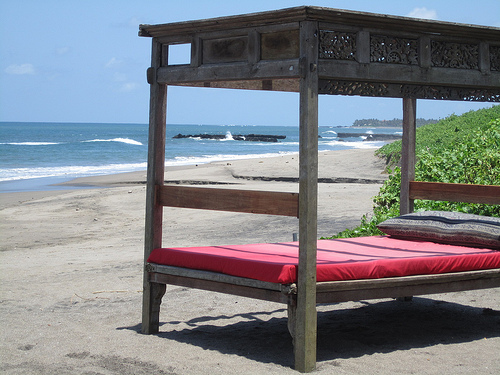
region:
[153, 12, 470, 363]
bed on beach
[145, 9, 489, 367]
bed on sand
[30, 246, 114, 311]
tan sand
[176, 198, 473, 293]
red mattress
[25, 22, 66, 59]
white clouds in blue sky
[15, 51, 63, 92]
white clouds in blue sky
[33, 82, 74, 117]
white clouds in blue sky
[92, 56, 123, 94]
white clouds in blue sky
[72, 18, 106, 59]
white clouds in blue sky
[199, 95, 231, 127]
white clouds in blue sky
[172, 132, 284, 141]
wall of rocks in ocean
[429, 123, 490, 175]
green grass on hill side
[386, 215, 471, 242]
grey and white pillows on red bed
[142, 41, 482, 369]
wooden bed on beach by ocean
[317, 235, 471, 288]
red bed mattress on wooden frame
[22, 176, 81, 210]
sandy beach by ocean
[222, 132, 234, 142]
waves crash against black rocks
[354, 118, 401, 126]
tree line in the distance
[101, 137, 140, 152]
white waves in blue ocean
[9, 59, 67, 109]
clear sky with few clouds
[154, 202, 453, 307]
the bed sheet is red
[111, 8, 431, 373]
a bed at the beach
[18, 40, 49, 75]
white clouds in blue sky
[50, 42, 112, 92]
white clouds in blue sky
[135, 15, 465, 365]
wooden bed on sand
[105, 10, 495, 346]
wooden bed on beach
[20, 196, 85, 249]
tan sand at beach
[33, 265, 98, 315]
tan sand at beach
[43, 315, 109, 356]
tan sand at beach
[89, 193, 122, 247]
tan sand at beach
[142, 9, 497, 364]
a wooden bed on a beach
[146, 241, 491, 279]
a red sheet on the bed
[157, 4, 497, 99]
a canopy over the bed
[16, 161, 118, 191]
white waves on the shore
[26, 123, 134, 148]
waves in the ocean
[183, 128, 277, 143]
rocks in the ocean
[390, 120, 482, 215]
green leafy bush behind the bed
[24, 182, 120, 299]
white sand on the beach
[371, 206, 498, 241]
a pillow on the bed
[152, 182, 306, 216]
a wooden support